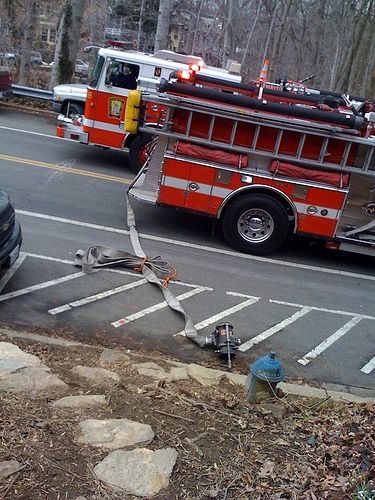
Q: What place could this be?
A: It is a road.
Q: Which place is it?
A: It is a road.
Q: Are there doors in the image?
A: Yes, there is a door.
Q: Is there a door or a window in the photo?
A: Yes, there is a door.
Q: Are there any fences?
A: No, there are no fences.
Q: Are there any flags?
A: No, there are no flags.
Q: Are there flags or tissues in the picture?
A: No, there are no flags or tissues.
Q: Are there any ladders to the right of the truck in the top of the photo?
A: Yes, there is a ladder to the right of the truck.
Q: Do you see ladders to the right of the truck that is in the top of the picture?
A: Yes, there is a ladder to the right of the truck.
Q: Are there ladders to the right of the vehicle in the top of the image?
A: Yes, there is a ladder to the right of the truck.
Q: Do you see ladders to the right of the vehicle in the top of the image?
A: Yes, there is a ladder to the right of the truck.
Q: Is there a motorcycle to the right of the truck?
A: No, there is a ladder to the right of the truck.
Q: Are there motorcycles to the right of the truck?
A: No, there is a ladder to the right of the truck.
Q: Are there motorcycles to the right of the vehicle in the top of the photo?
A: No, there is a ladder to the right of the truck.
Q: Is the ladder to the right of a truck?
A: Yes, the ladder is to the right of a truck.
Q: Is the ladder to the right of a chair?
A: No, the ladder is to the right of a truck.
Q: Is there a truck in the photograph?
A: Yes, there is a truck.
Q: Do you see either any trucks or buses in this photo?
A: Yes, there is a truck.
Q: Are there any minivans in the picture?
A: No, there are no minivans.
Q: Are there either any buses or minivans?
A: No, there are no minivans or buses.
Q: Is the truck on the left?
A: Yes, the truck is on the left of the image.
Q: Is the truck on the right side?
A: No, the truck is on the left of the image.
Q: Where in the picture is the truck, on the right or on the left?
A: The truck is on the left of the image.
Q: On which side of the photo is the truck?
A: The truck is on the left of the image.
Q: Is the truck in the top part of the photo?
A: Yes, the truck is in the top of the image.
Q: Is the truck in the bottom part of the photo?
A: No, the truck is in the top of the image.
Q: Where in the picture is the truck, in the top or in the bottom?
A: The truck is in the top of the image.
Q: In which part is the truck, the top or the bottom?
A: The truck is in the top of the image.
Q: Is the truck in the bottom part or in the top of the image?
A: The truck is in the top of the image.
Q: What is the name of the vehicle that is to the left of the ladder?
A: The vehicle is a truck.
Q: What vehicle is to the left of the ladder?
A: The vehicle is a truck.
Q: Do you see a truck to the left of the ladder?
A: Yes, there is a truck to the left of the ladder.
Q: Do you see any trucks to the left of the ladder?
A: Yes, there is a truck to the left of the ladder.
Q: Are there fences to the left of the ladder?
A: No, there is a truck to the left of the ladder.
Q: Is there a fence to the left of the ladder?
A: No, there is a truck to the left of the ladder.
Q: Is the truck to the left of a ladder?
A: Yes, the truck is to the left of a ladder.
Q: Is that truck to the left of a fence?
A: No, the truck is to the left of a ladder.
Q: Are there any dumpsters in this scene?
A: No, there are no dumpsters.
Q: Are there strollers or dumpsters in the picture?
A: No, there are no dumpsters or strollers.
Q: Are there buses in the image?
A: No, there are no buses.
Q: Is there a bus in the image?
A: No, there are no buses.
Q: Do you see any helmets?
A: No, there are no helmets.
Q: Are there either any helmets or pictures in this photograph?
A: No, there are no helmets or pictures.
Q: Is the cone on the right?
A: Yes, the cone is on the right of the image.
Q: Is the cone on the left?
A: No, the cone is on the right of the image.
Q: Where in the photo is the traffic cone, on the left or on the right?
A: The traffic cone is on the right of the image.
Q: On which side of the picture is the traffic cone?
A: The traffic cone is on the right of the image.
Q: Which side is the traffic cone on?
A: The traffic cone is on the right of the image.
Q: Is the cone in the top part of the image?
A: Yes, the cone is in the top of the image.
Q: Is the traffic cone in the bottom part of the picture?
A: No, the traffic cone is in the top of the image.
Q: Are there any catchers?
A: No, there are no catchers.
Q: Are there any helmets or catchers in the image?
A: No, there are no catchers or helmets.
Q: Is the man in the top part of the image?
A: Yes, the man is in the top of the image.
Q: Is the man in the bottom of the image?
A: No, the man is in the top of the image.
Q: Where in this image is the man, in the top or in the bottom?
A: The man is in the top of the image.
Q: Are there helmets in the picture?
A: No, there are no helmets.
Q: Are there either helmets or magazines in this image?
A: No, there are no helmets or magazines.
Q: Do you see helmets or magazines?
A: No, there are no helmets or magazines.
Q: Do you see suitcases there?
A: No, there are no suitcases.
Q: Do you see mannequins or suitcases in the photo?
A: No, there are no suitcases or mannequins.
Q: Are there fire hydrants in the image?
A: Yes, there is a fire hydrant.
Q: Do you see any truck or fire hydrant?
A: Yes, there is a fire hydrant.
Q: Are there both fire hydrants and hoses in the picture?
A: Yes, there are both a fire hydrant and a hose.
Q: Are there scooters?
A: No, there are no scooters.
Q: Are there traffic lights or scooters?
A: No, there are no scooters or traffic lights.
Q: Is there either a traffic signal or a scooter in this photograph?
A: No, there are no scooters or traffic lights.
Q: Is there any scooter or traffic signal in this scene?
A: No, there are no scooters or traffic lights.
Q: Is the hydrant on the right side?
A: Yes, the hydrant is on the right of the image.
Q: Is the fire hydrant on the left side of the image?
A: No, the fire hydrant is on the right of the image.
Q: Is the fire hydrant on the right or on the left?
A: The fire hydrant is on the right of the image.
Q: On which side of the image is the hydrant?
A: The hydrant is on the right of the image.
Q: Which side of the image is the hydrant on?
A: The hydrant is on the right of the image.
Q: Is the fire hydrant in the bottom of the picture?
A: Yes, the fire hydrant is in the bottom of the image.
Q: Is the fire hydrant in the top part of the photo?
A: No, the fire hydrant is in the bottom of the image.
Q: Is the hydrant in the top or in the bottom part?
A: The hydrant is in the bottom of the image.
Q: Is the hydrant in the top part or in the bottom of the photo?
A: The hydrant is in the bottom of the image.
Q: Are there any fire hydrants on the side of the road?
A: Yes, there is a fire hydrant on the side of the road.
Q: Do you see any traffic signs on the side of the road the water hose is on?
A: No, there is a fire hydrant on the side of the road.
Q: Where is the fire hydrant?
A: The fire hydrant is on the dirt.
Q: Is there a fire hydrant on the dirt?
A: Yes, there is a fire hydrant on the dirt.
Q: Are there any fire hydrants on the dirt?
A: Yes, there is a fire hydrant on the dirt.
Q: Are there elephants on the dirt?
A: No, there is a fire hydrant on the dirt.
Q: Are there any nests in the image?
A: No, there are no nests.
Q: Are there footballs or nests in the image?
A: No, there are no nests or footballs.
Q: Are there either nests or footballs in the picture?
A: No, there are no nests or footballs.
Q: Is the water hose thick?
A: Yes, the water hose is thick.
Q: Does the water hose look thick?
A: Yes, the water hose is thick.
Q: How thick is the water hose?
A: The water hose is thick.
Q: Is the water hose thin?
A: No, the water hose is thick.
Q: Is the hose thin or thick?
A: The hose is thick.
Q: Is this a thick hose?
A: Yes, this is a thick hose.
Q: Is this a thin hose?
A: No, this is a thick hose.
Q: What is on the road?
A: The water hose is on the road.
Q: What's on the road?
A: The water hose is on the road.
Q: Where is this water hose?
A: The water hose is on the road.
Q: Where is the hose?
A: The water hose is on the road.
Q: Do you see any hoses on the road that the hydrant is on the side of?
A: Yes, there is a hose on the road.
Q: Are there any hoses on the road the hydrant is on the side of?
A: Yes, there is a hose on the road.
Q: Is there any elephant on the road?
A: No, there is a hose on the road.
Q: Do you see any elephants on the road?
A: No, there is a hose on the road.